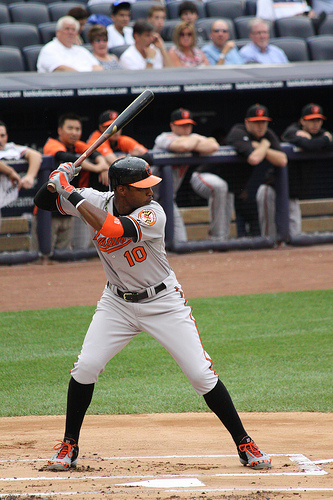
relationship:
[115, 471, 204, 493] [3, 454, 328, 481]
plate in box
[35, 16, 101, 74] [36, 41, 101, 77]
people wearing shirt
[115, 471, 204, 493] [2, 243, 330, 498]
plate on ground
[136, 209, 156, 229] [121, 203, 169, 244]
logo on sleeve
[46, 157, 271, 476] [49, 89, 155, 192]
man swinging bat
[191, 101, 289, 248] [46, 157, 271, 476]
players watching man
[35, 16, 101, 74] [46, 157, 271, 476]
people watching man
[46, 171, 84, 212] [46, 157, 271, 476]
glove on man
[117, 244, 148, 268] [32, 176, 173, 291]
ten on shirt